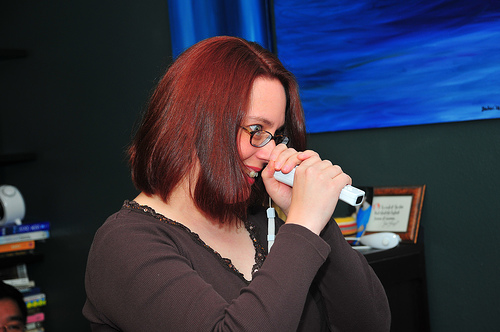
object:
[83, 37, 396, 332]
woman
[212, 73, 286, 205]
face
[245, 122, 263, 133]
eyes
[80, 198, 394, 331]
shirt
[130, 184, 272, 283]
neckline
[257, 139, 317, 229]
hands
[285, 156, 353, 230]
hands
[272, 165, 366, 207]
telescope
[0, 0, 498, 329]
wall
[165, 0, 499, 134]
abstract